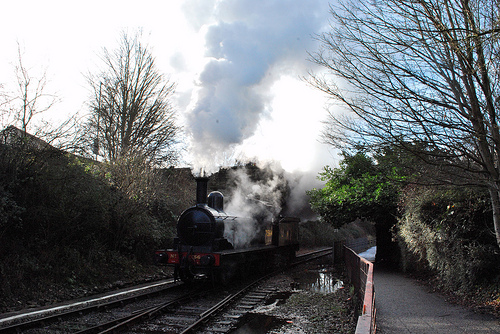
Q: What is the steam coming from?
A: Train.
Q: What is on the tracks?
A: A train.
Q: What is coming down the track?
A: Train.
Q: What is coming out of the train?
A: Steam.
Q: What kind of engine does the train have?
A: Steam.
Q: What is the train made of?
A: Metal.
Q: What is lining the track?
A: Trees.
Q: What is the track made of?
A: Metal.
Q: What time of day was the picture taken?
A: Afternoon.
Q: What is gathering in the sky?
A: Steam.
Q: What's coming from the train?
A: Smoke.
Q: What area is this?
A: Rural.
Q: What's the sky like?
A: Cloudy.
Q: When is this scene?
A: Late afternoon.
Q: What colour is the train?
A: Black.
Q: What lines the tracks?
A: Trees.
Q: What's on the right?
A: Walkway.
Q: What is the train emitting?
A: Smoke.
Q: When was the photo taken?
A: Daytime.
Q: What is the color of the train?
A: Black.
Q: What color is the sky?
A: Blue and white.